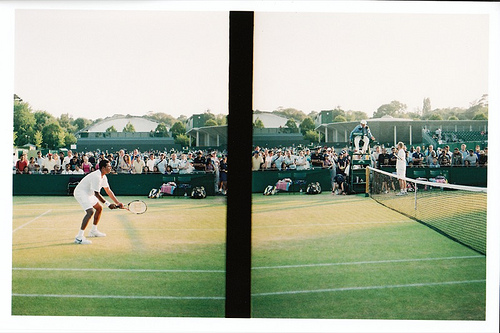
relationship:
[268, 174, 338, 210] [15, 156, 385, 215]
bags on court side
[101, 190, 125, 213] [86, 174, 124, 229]
sweatband on arm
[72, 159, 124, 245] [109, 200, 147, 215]
man holding tennis racket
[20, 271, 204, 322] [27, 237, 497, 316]
lines on floor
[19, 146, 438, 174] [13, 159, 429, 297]
spectators watching game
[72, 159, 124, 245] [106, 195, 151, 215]
man holding tennis racket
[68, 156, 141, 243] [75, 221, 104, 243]
man wearing shoes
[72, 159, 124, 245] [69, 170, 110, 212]
man wearing white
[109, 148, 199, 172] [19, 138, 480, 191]
people in audience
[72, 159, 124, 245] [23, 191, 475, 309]
man standing on tennis court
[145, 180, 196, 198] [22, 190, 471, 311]
bags on ground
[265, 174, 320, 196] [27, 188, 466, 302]
bags on ground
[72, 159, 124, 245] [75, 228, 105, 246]
man wearing shoes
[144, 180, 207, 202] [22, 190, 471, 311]
bags on ground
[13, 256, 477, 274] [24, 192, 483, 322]
line on tennis court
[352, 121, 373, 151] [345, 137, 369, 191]
referee sitting on chair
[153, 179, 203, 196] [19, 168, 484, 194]
bags on sideline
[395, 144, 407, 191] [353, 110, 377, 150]
someone speaking with referee